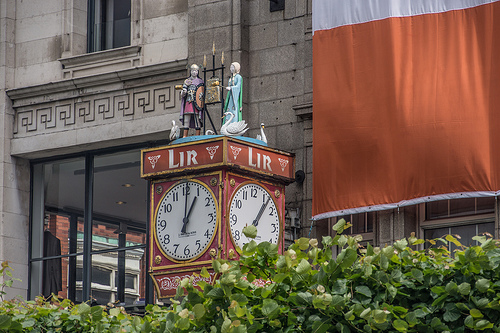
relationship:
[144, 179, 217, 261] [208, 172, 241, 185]
clock on tower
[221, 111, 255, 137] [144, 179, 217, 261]
swan on clock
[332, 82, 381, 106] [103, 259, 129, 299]
jacket in window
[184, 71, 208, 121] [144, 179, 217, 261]
statue on clock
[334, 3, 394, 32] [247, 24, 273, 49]
flag on building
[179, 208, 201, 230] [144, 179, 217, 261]
hand on clock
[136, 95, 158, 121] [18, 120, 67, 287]
design on doorway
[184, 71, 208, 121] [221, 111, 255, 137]
statue near swan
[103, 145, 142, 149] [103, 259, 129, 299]
frame on window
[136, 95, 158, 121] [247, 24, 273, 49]
design on building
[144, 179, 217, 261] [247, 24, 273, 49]
clock on building